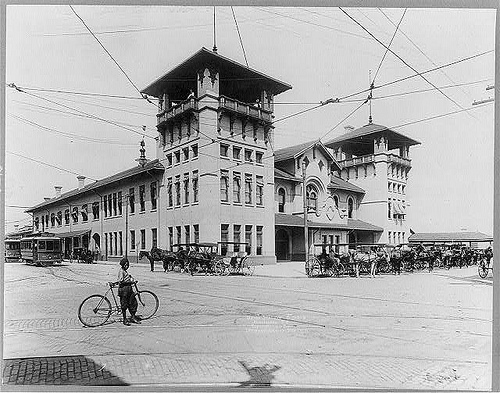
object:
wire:
[8, 81, 158, 101]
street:
[6, 275, 485, 388]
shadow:
[2, 355, 127, 386]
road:
[3, 276, 484, 388]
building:
[0, 47, 417, 265]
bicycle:
[78, 279, 160, 327]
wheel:
[77, 293, 113, 328]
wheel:
[127, 287, 160, 320]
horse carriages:
[217, 240, 254, 276]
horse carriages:
[305, 242, 351, 279]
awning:
[274, 212, 384, 232]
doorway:
[278, 231, 303, 277]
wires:
[6, 78, 164, 102]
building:
[142, 48, 289, 263]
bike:
[77, 281, 160, 327]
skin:
[126, 265, 129, 268]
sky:
[12, 13, 144, 133]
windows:
[129, 187, 137, 215]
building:
[31, 159, 274, 264]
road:
[162, 302, 233, 324]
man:
[117, 256, 142, 327]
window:
[220, 169, 230, 203]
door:
[277, 227, 304, 258]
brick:
[17, 360, 27, 370]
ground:
[36, 300, 91, 352]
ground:
[223, 344, 292, 386]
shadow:
[87, 348, 160, 360]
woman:
[118, 257, 140, 325]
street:
[154, 280, 418, 384]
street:
[299, 303, 489, 390]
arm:
[118, 268, 136, 285]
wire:
[77, 20, 167, 115]